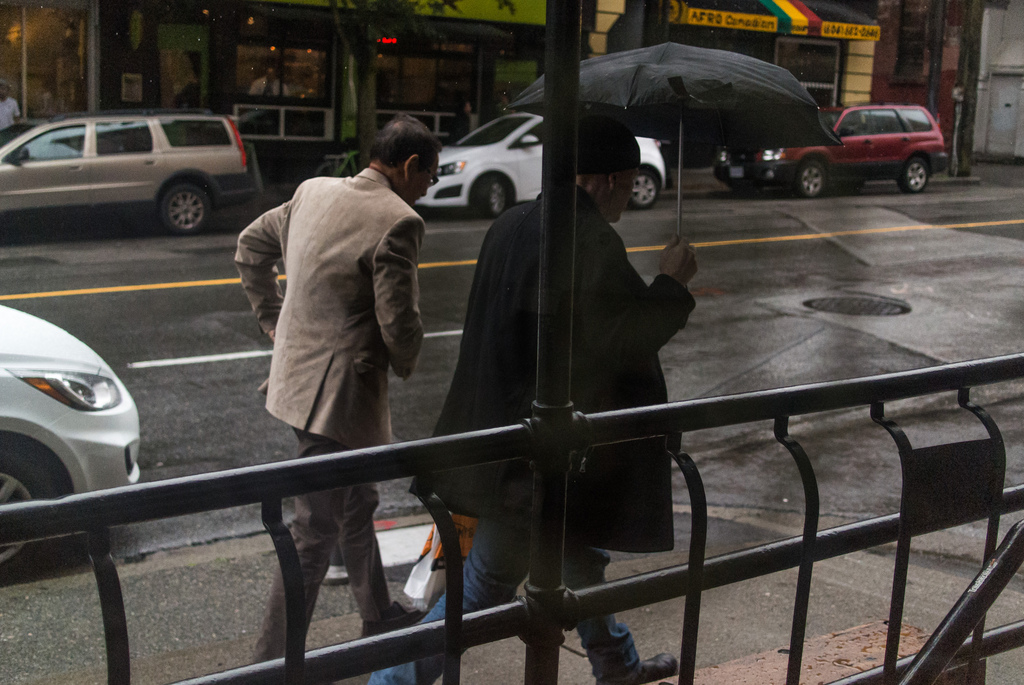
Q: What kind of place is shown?
A: It is a sidewalk.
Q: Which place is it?
A: It is a sidewalk.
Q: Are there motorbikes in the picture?
A: No, there are no motorbikes.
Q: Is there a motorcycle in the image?
A: No, there are no motorcycles.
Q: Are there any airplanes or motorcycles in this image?
A: No, there are no motorcycles or airplanes.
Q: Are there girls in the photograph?
A: No, there are no girls.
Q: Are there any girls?
A: No, there are no girls.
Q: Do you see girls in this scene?
A: No, there are no girls.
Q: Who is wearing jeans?
A: The man is wearing jeans.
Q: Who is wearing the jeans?
A: The man is wearing jeans.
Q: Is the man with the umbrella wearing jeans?
A: Yes, the man is wearing jeans.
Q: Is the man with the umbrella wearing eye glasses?
A: No, the man is wearing jeans.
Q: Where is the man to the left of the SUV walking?
A: The man is walking on the sidewalk.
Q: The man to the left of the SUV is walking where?
A: The man is walking on the sidewalk.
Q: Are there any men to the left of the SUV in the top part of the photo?
A: Yes, there is a man to the left of the SUV.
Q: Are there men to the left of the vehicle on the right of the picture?
A: Yes, there is a man to the left of the SUV.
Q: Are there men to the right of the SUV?
A: No, the man is to the left of the SUV.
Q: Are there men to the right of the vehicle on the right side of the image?
A: No, the man is to the left of the SUV.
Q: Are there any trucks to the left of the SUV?
A: No, there is a man to the left of the SUV.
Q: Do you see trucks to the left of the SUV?
A: No, there is a man to the left of the SUV.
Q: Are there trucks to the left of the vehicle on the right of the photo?
A: No, there is a man to the left of the SUV.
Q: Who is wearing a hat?
A: The man is wearing a hat.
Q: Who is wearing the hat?
A: The man is wearing a hat.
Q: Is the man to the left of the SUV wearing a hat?
A: Yes, the man is wearing a hat.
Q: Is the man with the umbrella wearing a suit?
A: No, the man is wearing a hat.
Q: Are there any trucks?
A: No, there are no trucks.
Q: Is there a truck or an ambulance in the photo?
A: No, there are no trucks or ambulances.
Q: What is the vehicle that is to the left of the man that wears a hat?
A: The vehicle is a car.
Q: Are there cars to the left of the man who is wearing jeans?
A: Yes, there is a car to the left of the man.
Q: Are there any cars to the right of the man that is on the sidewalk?
A: No, the car is to the left of the man.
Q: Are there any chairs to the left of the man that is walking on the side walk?
A: No, there is a car to the left of the man.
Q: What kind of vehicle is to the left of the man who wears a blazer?
A: The vehicle is a car.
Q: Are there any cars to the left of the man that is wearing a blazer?
A: Yes, there is a car to the left of the man.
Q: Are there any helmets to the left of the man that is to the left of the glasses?
A: No, there is a car to the left of the man.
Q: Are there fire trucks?
A: No, there are no fire trucks.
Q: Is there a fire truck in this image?
A: No, there are no fire trucks.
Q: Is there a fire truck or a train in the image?
A: No, there are no fire trucks or trains.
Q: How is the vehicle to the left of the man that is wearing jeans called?
A: The vehicle is a car.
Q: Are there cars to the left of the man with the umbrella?
A: Yes, there is a car to the left of the man.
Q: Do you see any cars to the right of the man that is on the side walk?
A: No, the car is to the left of the man.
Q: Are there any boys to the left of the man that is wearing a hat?
A: No, there is a car to the left of the man.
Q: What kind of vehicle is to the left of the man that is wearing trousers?
A: The vehicle is a car.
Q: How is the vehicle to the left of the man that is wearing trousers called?
A: The vehicle is a car.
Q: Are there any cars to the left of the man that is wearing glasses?
A: Yes, there is a car to the left of the man.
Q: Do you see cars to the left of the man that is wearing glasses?
A: Yes, there is a car to the left of the man.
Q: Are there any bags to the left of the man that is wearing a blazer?
A: No, there is a car to the left of the man.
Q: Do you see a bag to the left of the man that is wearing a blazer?
A: No, there is a car to the left of the man.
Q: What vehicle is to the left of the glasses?
A: The vehicle is a car.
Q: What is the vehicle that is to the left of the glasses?
A: The vehicle is a car.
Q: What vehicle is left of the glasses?
A: The vehicle is a car.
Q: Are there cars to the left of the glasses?
A: Yes, there is a car to the left of the glasses.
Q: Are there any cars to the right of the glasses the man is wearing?
A: No, the car is to the left of the glasses.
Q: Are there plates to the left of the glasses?
A: No, there is a car to the left of the glasses.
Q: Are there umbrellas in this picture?
A: Yes, there is an umbrella.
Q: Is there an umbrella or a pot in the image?
A: Yes, there is an umbrella.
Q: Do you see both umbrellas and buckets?
A: No, there is an umbrella but no buckets.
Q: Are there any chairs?
A: No, there are no chairs.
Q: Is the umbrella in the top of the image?
A: Yes, the umbrella is in the top of the image.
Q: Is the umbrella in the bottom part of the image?
A: No, the umbrella is in the top of the image.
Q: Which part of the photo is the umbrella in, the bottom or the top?
A: The umbrella is in the top of the image.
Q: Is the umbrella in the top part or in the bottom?
A: The umbrella is in the top of the image.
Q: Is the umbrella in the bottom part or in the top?
A: The umbrella is in the top of the image.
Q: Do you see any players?
A: No, there are no players.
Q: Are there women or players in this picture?
A: No, there are no players or women.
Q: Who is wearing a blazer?
A: The man is wearing a blazer.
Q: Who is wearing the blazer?
A: The man is wearing a blazer.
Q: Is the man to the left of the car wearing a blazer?
A: Yes, the man is wearing a blazer.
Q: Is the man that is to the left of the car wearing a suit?
A: No, the man is wearing a blazer.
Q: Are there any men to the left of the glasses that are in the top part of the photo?
A: Yes, there is a man to the left of the glasses.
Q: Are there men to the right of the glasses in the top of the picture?
A: No, the man is to the left of the glasses.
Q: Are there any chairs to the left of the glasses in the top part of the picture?
A: No, there is a man to the left of the glasses.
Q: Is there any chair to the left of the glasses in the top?
A: No, there is a man to the left of the glasses.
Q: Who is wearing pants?
A: The man is wearing pants.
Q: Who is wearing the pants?
A: The man is wearing pants.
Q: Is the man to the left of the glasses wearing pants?
A: Yes, the man is wearing pants.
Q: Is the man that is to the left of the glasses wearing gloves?
A: No, the man is wearing pants.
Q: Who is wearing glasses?
A: The man is wearing glasses.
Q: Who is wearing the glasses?
A: The man is wearing glasses.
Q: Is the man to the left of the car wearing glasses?
A: Yes, the man is wearing glasses.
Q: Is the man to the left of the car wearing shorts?
A: No, the man is wearing glasses.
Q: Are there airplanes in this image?
A: No, there are no airplanes.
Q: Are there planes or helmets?
A: No, there are no planes or helmets.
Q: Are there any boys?
A: No, there are no boys.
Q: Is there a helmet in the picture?
A: No, there are no helmets.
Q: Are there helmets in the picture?
A: No, there are no helmets.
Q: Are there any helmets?
A: No, there are no helmets.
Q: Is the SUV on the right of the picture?
A: Yes, the SUV is on the right of the image.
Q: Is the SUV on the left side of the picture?
A: No, the SUV is on the right of the image.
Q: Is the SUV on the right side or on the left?
A: The SUV is on the right of the image.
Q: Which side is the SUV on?
A: The SUV is on the right of the image.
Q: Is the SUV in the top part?
A: Yes, the SUV is in the top of the image.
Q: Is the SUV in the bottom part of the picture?
A: No, the SUV is in the top of the image.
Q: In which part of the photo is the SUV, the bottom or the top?
A: The SUV is in the top of the image.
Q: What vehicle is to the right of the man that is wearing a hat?
A: The vehicle is a SUV.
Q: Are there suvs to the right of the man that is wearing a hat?
A: Yes, there is a SUV to the right of the man.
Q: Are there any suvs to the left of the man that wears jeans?
A: No, the SUV is to the right of the man.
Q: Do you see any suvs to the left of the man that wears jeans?
A: No, the SUV is to the right of the man.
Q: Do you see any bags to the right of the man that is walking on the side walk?
A: No, there is a SUV to the right of the man.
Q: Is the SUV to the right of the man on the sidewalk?
A: Yes, the SUV is to the right of the man.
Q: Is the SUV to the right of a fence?
A: No, the SUV is to the right of the man.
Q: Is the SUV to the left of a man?
A: No, the SUV is to the right of a man.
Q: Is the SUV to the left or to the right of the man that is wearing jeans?
A: The SUV is to the right of the man.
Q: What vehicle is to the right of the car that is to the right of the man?
A: The vehicle is a SUV.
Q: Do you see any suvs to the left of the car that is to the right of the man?
A: No, the SUV is to the right of the car.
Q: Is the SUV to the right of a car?
A: Yes, the SUV is to the right of a car.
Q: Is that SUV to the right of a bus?
A: No, the SUV is to the right of a car.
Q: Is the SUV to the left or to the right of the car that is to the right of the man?
A: The SUV is to the right of the car.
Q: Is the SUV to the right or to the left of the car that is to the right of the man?
A: The SUV is to the right of the car.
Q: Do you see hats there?
A: Yes, there is a hat.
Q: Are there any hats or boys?
A: Yes, there is a hat.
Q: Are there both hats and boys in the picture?
A: No, there is a hat but no boys.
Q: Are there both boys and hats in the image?
A: No, there is a hat but no boys.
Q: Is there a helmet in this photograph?
A: No, there are no helmets.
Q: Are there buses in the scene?
A: No, there are no buses.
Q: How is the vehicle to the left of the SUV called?
A: The vehicle is a car.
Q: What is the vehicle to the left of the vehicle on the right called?
A: The vehicle is a car.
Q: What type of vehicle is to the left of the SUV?
A: The vehicle is a car.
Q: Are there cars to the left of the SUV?
A: Yes, there is a car to the left of the SUV.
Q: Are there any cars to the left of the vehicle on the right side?
A: Yes, there is a car to the left of the SUV.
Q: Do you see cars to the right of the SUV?
A: No, the car is to the left of the SUV.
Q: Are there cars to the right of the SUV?
A: No, the car is to the left of the SUV.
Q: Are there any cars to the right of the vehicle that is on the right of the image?
A: No, the car is to the left of the SUV.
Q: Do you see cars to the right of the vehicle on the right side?
A: No, the car is to the left of the SUV.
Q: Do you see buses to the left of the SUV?
A: No, there is a car to the left of the SUV.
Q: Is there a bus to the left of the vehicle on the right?
A: No, there is a car to the left of the SUV.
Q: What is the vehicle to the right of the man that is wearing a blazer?
A: The vehicle is a car.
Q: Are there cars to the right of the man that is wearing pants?
A: Yes, there is a car to the right of the man.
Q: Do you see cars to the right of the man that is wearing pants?
A: Yes, there is a car to the right of the man.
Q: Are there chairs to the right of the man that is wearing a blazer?
A: No, there is a car to the right of the man.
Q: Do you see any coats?
A: Yes, there is a coat.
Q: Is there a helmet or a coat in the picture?
A: Yes, there is a coat.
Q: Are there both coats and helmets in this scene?
A: No, there is a coat but no helmets.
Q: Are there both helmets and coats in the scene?
A: No, there is a coat but no helmets.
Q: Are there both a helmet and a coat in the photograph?
A: No, there is a coat but no helmets.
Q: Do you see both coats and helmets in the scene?
A: No, there is a coat but no helmets.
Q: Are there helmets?
A: No, there are no helmets.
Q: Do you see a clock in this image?
A: No, there are no clocks.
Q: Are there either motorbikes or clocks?
A: No, there are no clocks or motorbikes.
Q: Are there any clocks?
A: No, there are no clocks.